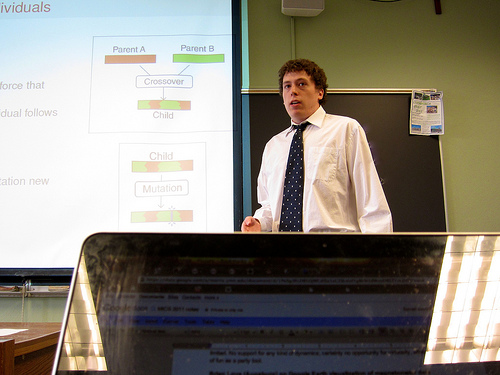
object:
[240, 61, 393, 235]
guy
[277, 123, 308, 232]
tie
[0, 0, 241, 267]
information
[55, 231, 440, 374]
screen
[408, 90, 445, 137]
poster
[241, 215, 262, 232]
right hand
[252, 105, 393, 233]
shirt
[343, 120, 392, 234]
sleeve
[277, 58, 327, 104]
hair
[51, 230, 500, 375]
laptop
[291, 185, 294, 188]
dots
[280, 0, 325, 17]
speaker box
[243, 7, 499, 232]
wall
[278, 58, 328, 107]
afro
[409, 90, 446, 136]
paper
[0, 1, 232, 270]
screen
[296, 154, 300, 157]
spots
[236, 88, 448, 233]
blackboard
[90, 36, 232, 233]
graph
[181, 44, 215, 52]
parent b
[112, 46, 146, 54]
parent a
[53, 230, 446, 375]
foreground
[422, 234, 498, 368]
light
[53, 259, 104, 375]
light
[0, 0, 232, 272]
spreadsheet